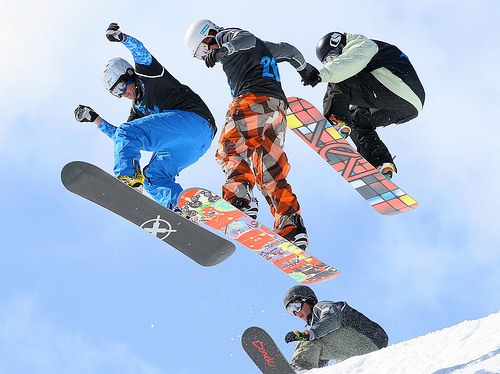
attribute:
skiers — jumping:
[59, 19, 424, 373]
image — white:
[140, 214, 177, 242]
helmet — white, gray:
[183, 19, 220, 61]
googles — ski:
[111, 79, 130, 99]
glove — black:
[203, 46, 226, 68]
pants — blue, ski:
[112, 109, 216, 213]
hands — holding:
[284, 45, 368, 86]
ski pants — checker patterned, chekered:
[217, 92, 309, 247]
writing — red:
[251, 337, 274, 368]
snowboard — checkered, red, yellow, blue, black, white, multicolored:
[287, 96, 418, 216]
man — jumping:
[75, 21, 217, 230]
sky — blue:
[2, 3, 490, 372]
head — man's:
[101, 54, 141, 102]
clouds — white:
[3, 291, 163, 371]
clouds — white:
[0, 292, 150, 372]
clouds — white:
[278, 3, 477, 302]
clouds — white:
[373, 210, 484, 310]